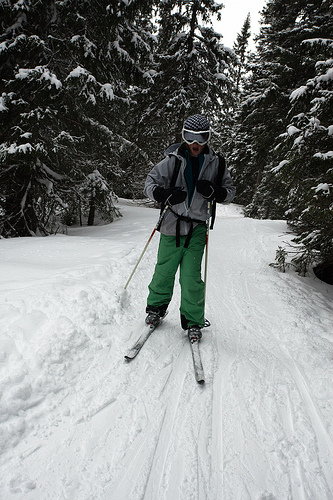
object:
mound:
[0, 307, 81, 430]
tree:
[2, 0, 62, 238]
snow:
[66, 65, 87, 79]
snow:
[193, 344, 202, 369]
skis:
[125, 310, 169, 358]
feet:
[145, 314, 160, 325]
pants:
[146, 226, 207, 323]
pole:
[125, 204, 168, 290]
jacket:
[146, 142, 237, 237]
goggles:
[182, 129, 211, 146]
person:
[122, 113, 235, 342]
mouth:
[193, 147, 199, 151]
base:
[88, 204, 94, 228]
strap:
[176, 219, 180, 247]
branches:
[84, 117, 121, 145]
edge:
[198, 345, 205, 382]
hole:
[3, 475, 22, 498]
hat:
[184, 115, 210, 131]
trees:
[278, 0, 333, 284]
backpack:
[172, 157, 182, 187]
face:
[188, 132, 205, 156]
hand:
[154, 187, 187, 206]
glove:
[154, 186, 187, 205]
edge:
[245, 210, 288, 228]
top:
[237, 11, 251, 42]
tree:
[230, 12, 250, 129]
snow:
[0, 236, 333, 495]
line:
[291, 371, 329, 495]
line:
[210, 380, 214, 497]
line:
[144, 406, 167, 498]